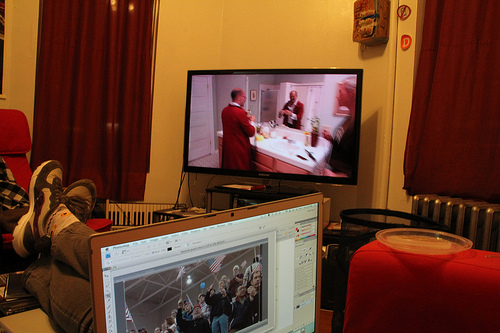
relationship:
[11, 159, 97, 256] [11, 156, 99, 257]
sneakers on feet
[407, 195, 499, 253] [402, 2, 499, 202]
radiator under curtains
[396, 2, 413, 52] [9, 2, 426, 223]
stickers on wall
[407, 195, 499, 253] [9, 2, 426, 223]
radiator near wall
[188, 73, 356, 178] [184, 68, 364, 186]
bathroom scene shown on television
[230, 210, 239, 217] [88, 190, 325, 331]
webcam on laptop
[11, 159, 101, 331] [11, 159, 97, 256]
person wearing sneakers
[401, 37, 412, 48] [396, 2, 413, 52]
letter d on stickers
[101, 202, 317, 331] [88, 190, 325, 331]
monitor of laptop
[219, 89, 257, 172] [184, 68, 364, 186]
man on television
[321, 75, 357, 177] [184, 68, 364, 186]
woman on television